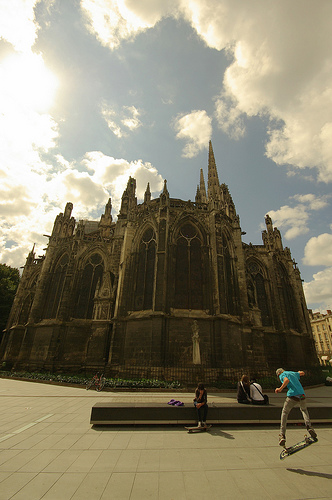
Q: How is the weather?
A: It is partly cloudy.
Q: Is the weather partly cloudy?
A: Yes, it is partly cloudy.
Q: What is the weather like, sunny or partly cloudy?
A: It is partly cloudy.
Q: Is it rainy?
A: No, it is partly cloudy.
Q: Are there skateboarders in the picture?
A: Yes, there is a skateboarder.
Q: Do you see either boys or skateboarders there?
A: Yes, there is a skateboarder.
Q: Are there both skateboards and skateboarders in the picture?
A: Yes, there are both a skateboarder and a skateboard.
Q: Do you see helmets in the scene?
A: No, there are no helmets.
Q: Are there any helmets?
A: No, there are no helmets.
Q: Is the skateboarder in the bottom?
A: Yes, the skateboarder is in the bottom of the image.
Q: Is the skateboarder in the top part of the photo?
A: No, the skateboarder is in the bottom of the image.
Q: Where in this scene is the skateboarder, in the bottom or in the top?
A: The skateboarder is in the bottom of the image.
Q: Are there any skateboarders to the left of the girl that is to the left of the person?
A: Yes, there is a skateboarder to the left of the girl.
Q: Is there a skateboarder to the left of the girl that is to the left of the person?
A: Yes, there is a skateboarder to the left of the girl.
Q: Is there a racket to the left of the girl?
A: No, there is a skateboarder to the left of the girl.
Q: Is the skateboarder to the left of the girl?
A: Yes, the skateboarder is to the left of the girl.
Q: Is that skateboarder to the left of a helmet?
A: No, the skateboarder is to the left of the girl.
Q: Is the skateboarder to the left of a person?
A: Yes, the skateboarder is to the left of a person.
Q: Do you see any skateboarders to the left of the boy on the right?
A: Yes, there is a skateboarder to the left of the boy.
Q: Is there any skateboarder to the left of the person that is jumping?
A: Yes, there is a skateboarder to the left of the boy.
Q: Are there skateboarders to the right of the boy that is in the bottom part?
A: No, the skateboarder is to the left of the boy.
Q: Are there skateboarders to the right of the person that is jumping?
A: No, the skateboarder is to the left of the boy.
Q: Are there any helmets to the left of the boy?
A: No, there is a skateboarder to the left of the boy.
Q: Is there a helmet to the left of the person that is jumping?
A: No, there is a skateboarder to the left of the boy.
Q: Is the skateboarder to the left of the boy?
A: Yes, the skateboarder is to the left of the boy.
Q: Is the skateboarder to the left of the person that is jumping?
A: Yes, the skateboarder is to the left of the boy.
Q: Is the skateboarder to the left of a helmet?
A: No, the skateboarder is to the left of the boy.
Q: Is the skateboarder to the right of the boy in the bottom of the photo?
A: No, the skateboarder is to the left of the boy.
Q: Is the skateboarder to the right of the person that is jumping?
A: No, the skateboarder is to the left of the boy.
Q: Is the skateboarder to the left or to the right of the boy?
A: The skateboarder is to the left of the boy.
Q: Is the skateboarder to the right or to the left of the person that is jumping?
A: The skateboarder is to the left of the boy.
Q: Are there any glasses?
A: No, there are no glasses.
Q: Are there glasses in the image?
A: No, there are no glasses.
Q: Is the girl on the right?
A: Yes, the girl is on the right of the image.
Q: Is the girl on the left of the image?
A: No, the girl is on the right of the image.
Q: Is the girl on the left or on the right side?
A: The girl is on the right of the image.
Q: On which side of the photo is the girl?
A: The girl is on the right of the image.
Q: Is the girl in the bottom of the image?
A: Yes, the girl is in the bottom of the image.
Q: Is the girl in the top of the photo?
A: No, the girl is in the bottom of the image.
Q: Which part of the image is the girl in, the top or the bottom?
A: The girl is in the bottom of the image.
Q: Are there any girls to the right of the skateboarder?
A: Yes, there is a girl to the right of the skateboarder.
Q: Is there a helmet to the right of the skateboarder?
A: No, there is a girl to the right of the skateboarder.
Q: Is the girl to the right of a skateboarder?
A: Yes, the girl is to the right of a skateboarder.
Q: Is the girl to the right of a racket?
A: No, the girl is to the right of a skateboarder.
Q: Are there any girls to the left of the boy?
A: Yes, there is a girl to the left of the boy.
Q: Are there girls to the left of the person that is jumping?
A: Yes, there is a girl to the left of the boy.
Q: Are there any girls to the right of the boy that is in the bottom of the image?
A: No, the girl is to the left of the boy.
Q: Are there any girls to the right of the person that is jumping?
A: No, the girl is to the left of the boy.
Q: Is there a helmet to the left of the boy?
A: No, there is a girl to the left of the boy.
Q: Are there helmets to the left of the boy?
A: No, there is a girl to the left of the boy.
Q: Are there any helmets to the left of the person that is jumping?
A: No, there is a girl to the left of the boy.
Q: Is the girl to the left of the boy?
A: Yes, the girl is to the left of the boy.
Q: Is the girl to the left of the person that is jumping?
A: Yes, the girl is to the left of the boy.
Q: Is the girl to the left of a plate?
A: No, the girl is to the left of the boy.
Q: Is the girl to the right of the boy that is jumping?
A: No, the girl is to the left of the boy.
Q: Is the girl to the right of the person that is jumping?
A: No, the girl is to the left of the boy.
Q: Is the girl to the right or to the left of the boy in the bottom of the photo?
A: The girl is to the left of the boy.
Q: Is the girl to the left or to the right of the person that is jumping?
A: The girl is to the left of the boy.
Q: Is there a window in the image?
A: Yes, there is a window.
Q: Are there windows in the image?
A: Yes, there is a window.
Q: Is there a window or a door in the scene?
A: Yes, there is a window.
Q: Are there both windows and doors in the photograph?
A: No, there is a window but no doors.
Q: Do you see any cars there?
A: No, there are no cars.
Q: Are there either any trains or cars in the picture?
A: No, there are no cars or trains.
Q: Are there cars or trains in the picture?
A: No, there are no cars or trains.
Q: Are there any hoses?
A: No, there are no hoses.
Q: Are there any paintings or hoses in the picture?
A: No, there are no hoses or paintings.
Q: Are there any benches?
A: Yes, there is a bench.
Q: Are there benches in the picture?
A: Yes, there is a bench.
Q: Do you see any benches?
A: Yes, there is a bench.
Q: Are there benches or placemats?
A: Yes, there is a bench.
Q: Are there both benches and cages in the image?
A: No, there is a bench but no cages.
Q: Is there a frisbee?
A: No, there are no frisbees.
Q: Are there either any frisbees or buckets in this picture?
A: No, there are no frisbees or buckets.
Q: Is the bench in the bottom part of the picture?
A: Yes, the bench is in the bottom of the image.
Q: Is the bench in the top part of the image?
A: No, the bench is in the bottom of the image.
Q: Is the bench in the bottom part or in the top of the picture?
A: The bench is in the bottom of the image.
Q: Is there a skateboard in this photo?
A: Yes, there is a skateboard.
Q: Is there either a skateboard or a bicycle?
A: Yes, there is a skateboard.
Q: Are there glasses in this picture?
A: No, there are no glasses.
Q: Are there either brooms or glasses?
A: No, there are no glasses or brooms.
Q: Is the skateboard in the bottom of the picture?
A: Yes, the skateboard is in the bottom of the image.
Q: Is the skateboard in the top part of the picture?
A: No, the skateboard is in the bottom of the image.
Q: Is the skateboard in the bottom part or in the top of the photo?
A: The skateboard is in the bottom of the image.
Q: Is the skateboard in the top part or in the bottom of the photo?
A: The skateboard is in the bottom of the image.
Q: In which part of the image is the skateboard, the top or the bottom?
A: The skateboard is in the bottom of the image.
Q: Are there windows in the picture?
A: Yes, there are windows.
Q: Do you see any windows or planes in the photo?
A: Yes, there are windows.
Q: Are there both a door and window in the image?
A: No, there are windows but no doors.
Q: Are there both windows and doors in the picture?
A: No, there are windows but no doors.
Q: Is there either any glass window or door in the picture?
A: Yes, there are glass windows.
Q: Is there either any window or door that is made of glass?
A: Yes, the windows are made of glass.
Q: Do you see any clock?
A: No, there are no clocks.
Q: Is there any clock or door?
A: No, there are no clocks or doors.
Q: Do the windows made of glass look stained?
A: Yes, the windows are stained.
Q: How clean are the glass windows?
A: The windows are stained.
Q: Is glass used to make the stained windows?
A: Yes, the windows are made of glass.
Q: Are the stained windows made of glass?
A: Yes, the windows are made of glass.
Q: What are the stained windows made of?
A: The windows are made of glass.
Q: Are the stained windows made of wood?
A: No, the windows are made of glass.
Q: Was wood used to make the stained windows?
A: No, the windows are made of glass.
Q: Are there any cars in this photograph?
A: No, there are no cars.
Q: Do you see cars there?
A: No, there are no cars.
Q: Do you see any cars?
A: No, there are no cars.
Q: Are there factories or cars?
A: No, there are no cars or factories.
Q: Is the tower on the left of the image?
A: Yes, the tower is on the left of the image.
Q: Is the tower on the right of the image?
A: No, the tower is on the left of the image.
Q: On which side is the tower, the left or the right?
A: The tower is on the left of the image.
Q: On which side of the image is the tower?
A: The tower is on the left of the image.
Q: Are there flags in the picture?
A: No, there are no flags.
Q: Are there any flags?
A: No, there are no flags.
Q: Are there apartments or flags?
A: No, there are no flags or apartments.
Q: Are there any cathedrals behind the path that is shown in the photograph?
A: Yes, there is a cathedral behind the path.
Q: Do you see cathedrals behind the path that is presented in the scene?
A: Yes, there is a cathedral behind the path.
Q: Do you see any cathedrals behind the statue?
A: Yes, there is a cathedral behind the statue.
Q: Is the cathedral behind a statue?
A: Yes, the cathedral is behind a statue.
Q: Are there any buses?
A: No, there are no buses.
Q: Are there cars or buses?
A: No, there are no buses or cars.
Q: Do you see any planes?
A: No, there are no planes.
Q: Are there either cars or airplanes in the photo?
A: No, there are no airplanes or cars.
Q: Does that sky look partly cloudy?
A: Yes, the sky is partly cloudy.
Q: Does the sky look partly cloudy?
A: Yes, the sky is partly cloudy.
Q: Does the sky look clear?
A: No, the sky is partly cloudy.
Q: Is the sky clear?
A: No, the sky is partly cloudy.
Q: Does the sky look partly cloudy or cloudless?
A: The sky is partly cloudy.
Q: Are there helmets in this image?
A: No, there are no helmets.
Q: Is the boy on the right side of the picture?
A: Yes, the boy is on the right of the image.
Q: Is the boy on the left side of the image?
A: No, the boy is on the right of the image.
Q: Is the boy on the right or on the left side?
A: The boy is on the right of the image.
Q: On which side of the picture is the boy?
A: The boy is on the right of the image.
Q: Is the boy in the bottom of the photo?
A: Yes, the boy is in the bottom of the image.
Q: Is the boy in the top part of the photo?
A: No, the boy is in the bottom of the image.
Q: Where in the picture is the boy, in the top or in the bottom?
A: The boy is in the bottom of the image.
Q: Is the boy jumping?
A: Yes, the boy is jumping.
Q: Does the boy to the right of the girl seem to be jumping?
A: Yes, the boy is jumping.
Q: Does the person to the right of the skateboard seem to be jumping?
A: Yes, the boy is jumping.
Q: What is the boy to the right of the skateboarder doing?
A: The boy is jumping.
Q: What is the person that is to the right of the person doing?
A: The boy is jumping.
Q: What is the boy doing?
A: The boy is jumping.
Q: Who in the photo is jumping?
A: The boy is jumping.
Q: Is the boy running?
A: No, the boy is jumping.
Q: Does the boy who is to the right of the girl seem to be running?
A: No, the boy is jumping.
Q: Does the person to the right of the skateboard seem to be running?
A: No, the boy is jumping.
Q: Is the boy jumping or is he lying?
A: The boy is jumping.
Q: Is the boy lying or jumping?
A: The boy is jumping.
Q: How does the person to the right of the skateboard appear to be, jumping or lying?
A: The boy is jumping.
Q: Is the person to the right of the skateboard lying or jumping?
A: The boy is jumping.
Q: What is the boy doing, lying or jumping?
A: The boy is jumping.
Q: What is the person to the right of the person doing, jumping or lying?
A: The boy is jumping.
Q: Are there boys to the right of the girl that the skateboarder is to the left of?
A: Yes, there is a boy to the right of the girl.